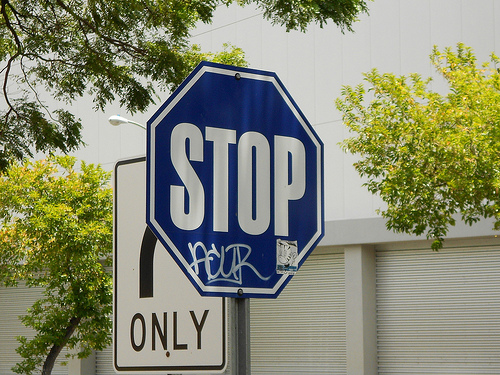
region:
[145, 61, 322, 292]
a blue and white sign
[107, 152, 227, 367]
a white and black sign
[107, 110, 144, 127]
a white street light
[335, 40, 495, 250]
leaves to the right of the signs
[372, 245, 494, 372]
farthest right garage door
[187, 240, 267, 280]
white graffiti on the stop sign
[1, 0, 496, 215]
the clear sky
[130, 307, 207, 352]
the word on the black and white sign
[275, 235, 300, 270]
the square sticker on the stop sign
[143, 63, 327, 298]
the eight sided sign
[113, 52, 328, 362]
one traffic sign partly covering another sign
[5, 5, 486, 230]
white paneled wall of building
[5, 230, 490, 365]
closed gates of horizontal ridged metal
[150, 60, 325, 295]
white graffiti and sticker on sign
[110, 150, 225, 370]
black curve over word on white sign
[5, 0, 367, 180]
tree with dark green branches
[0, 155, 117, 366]
green and yellow leaves on curved brown trunk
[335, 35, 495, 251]
light colored leaves on branches over building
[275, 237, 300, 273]
black and white drawing on square sticker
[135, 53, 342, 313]
this is a sign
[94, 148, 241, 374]
this is a sign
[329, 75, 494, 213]
this is a branch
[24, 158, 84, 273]
this is a branch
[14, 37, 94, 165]
this is a branch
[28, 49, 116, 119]
this is a branch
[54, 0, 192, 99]
this is a branch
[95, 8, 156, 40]
this is a branch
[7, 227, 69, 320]
this is a branch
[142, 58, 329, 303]
blue and white stop sign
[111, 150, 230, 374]
right turn only sign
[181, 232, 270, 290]
grafitti on a stop sign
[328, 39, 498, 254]
green leaves of a tree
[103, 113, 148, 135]
top of a street lamp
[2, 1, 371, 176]
tree branches and leaves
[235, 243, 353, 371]
roller shutter door in a building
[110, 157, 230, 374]
black and white road sign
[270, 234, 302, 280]
sticker on a stop sign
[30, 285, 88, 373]
trunk of a tree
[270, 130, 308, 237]
white letter on a sign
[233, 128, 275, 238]
white letter on a sign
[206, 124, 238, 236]
white letter on a sign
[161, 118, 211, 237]
white letter on a sign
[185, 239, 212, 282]
white letter on a sign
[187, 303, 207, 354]
black letter on a sign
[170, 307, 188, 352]
black letter on a sign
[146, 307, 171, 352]
black letter on a sign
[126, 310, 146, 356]
black letter on a sign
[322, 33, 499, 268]
tree near a building